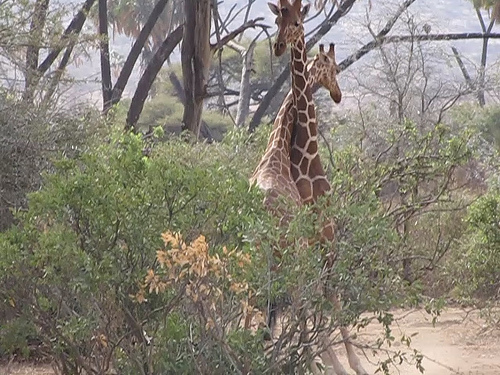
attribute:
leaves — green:
[17, 142, 215, 268]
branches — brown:
[15, 302, 370, 374]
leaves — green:
[147, 144, 264, 254]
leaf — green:
[398, 119, 422, 139]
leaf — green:
[144, 121, 167, 140]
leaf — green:
[461, 205, 481, 228]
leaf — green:
[123, 187, 148, 205]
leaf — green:
[93, 258, 120, 272]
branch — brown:
[261, 234, 276, 339]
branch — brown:
[384, 303, 423, 322]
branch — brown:
[379, 167, 456, 228]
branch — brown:
[167, 189, 200, 219]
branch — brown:
[100, 217, 125, 259]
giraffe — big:
[270, 0, 318, 230]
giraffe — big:
[249, 46, 344, 233]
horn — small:
[318, 42, 325, 54]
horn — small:
[328, 41, 336, 53]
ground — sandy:
[313, 306, 495, 373]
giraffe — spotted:
[262, 3, 311, 80]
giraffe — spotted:
[311, 40, 353, 108]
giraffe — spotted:
[245, 2, 362, 238]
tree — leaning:
[334, 2, 494, 77]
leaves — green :
[344, 124, 494, 254]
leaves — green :
[345, 227, 376, 264]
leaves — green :
[120, 141, 136, 154]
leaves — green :
[37, 234, 75, 266]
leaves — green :
[80, 185, 130, 224]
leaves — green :
[149, 155, 188, 204]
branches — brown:
[383, 147, 480, 230]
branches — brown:
[373, 131, 399, 187]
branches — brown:
[271, 298, 323, 359]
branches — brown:
[119, 305, 156, 365]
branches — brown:
[6, 270, 66, 326]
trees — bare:
[23, 0, 208, 143]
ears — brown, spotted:
[316, 39, 337, 58]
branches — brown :
[133, 127, 257, 282]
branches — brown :
[370, 76, 452, 246]